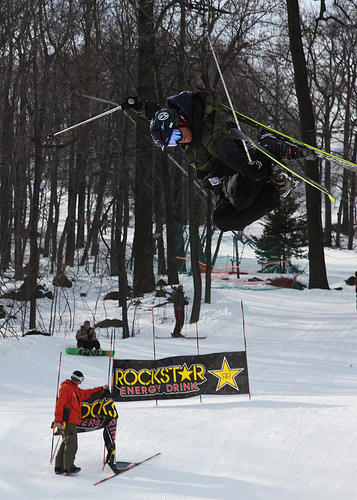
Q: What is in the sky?
A: Clouds.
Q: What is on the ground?
A: Snow.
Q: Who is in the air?
A: A man.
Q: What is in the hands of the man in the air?
A: A pair of skis.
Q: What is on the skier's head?
A: Helmet.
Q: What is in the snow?
A: A pole.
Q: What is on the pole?
A: A sign.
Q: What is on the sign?
A: Lettering.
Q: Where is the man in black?
A: In the air.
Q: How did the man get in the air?
A: He jumped off a ski jump.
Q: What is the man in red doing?
A: Fixing a banner.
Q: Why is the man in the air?
A: He is doing a ski jump.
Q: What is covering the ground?
A: Snow.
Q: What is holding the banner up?
A: Poles.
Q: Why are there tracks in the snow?
A: People skied there.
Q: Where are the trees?
A: Next to the ski trail.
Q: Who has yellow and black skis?
A: The man in the air.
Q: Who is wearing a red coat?
A: The man.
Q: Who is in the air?
A: The skier.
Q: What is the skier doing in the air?
A: Tricks.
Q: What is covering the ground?
A: Snow.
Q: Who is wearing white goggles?
A: Man in red.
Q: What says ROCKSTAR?
A: Banner.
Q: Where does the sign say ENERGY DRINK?
A: Under ROCKSTAR.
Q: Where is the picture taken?
A: At a ski slope.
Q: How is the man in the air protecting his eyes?
A: He's wearing sunglasses.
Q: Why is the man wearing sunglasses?
A: To protect his eyes.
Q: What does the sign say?
A: Rockstar.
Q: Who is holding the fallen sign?
A: The man in the red jacket.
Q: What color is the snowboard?
A: Green.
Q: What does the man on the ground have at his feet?
A: A snow board.